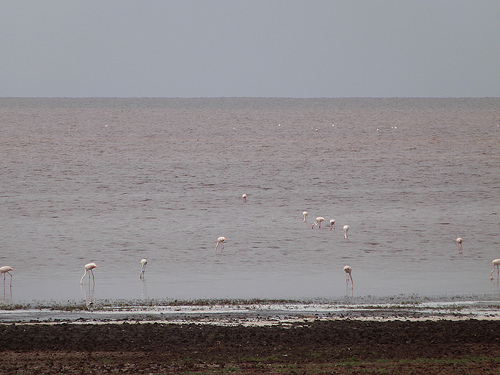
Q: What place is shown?
A: It is an ocean.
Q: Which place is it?
A: It is an ocean.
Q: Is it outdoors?
A: Yes, it is outdoors.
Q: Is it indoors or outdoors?
A: It is outdoors.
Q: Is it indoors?
A: No, it is outdoors.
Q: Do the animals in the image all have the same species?
A: No, they are swans and birds.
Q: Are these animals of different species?
A: Yes, they are swans and birds.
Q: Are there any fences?
A: No, there are no fences.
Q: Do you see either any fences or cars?
A: No, there are no fences or cars.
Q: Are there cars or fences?
A: No, there are no fences or cars.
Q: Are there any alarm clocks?
A: No, there are no alarm clocks.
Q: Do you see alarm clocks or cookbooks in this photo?
A: No, there are no alarm clocks or cookbooks.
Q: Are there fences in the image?
A: No, there are no fences.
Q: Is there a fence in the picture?
A: No, there are no fences.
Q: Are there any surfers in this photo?
A: No, there are no surfers.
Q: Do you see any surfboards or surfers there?
A: No, there are no surfers or surfboards.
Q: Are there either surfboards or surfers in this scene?
A: No, there are no surfers or surfboards.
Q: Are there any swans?
A: Yes, there is a swan.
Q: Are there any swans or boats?
A: Yes, there is a swan.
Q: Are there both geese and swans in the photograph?
A: No, there is a swan but no geese.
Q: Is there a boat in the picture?
A: No, there are no boats.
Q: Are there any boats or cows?
A: No, there are no boats or cows.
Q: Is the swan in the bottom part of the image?
A: Yes, the swan is in the bottom of the image.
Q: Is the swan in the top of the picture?
A: No, the swan is in the bottom of the image.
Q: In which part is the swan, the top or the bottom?
A: The swan is in the bottom of the image.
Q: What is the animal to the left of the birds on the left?
A: The animal is a swan.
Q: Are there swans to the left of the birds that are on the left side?
A: Yes, there is a swan to the left of the birds.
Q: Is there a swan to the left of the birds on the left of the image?
A: Yes, there is a swan to the left of the birds.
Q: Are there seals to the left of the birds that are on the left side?
A: No, there is a swan to the left of the birds.